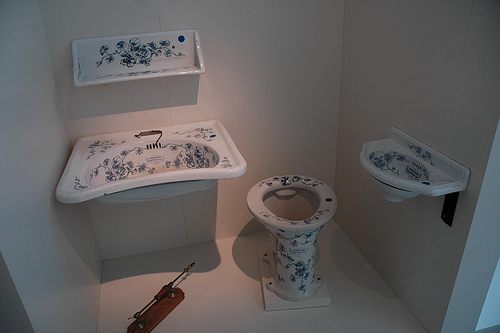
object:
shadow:
[328, 229, 407, 300]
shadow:
[67, 70, 198, 123]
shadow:
[65, 177, 220, 284]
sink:
[54, 119, 249, 205]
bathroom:
[1, 2, 499, 332]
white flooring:
[192, 282, 256, 317]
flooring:
[342, 270, 383, 322]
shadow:
[231, 215, 321, 281]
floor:
[101, 219, 429, 329]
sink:
[357, 126, 470, 202]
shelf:
[65, 27, 207, 86]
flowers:
[95, 37, 187, 68]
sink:
[355, 113, 477, 220]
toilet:
[247, 176, 338, 312]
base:
[258, 245, 331, 311]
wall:
[1, 3, 105, 332]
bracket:
[441, 192, 460, 228]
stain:
[284, 202, 306, 219]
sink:
[43, 106, 249, 220]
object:
[126, 262, 194, 333]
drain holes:
[412, 162, 415, 166]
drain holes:
[146, 145, 148, 150]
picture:
[71, 27, 210, 87]